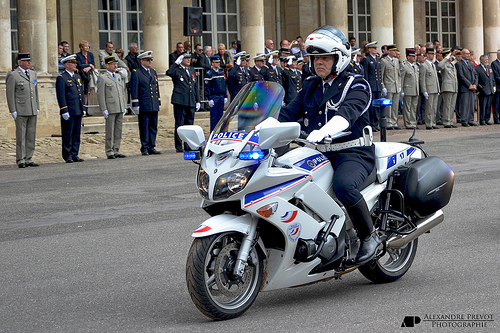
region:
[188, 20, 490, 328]
police on motorcycle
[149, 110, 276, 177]
blue lights flashing on motorcycle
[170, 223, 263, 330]
front tire of motorcycle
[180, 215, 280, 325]
front cover of tire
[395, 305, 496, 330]
watermark of photographer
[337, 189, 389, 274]
black motorcycle boots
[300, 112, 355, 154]
white gloves of officer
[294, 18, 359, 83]
officer's helmet on head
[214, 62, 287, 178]
shield on motorcycle for protection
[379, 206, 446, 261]
chrome exhaust pipe on bike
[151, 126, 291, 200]
flashing led lights on police motorcycle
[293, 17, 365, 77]
man wearing helmet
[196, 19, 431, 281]
police officer on motorcycle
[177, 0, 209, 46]
speaker for crowd to hear whats being said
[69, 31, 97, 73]
Woman in red shirt with blue jacket watching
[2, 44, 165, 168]
men of forces wearing the dress uniforms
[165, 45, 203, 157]
man standing saluting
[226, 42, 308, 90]
3 men saluting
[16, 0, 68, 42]
column of building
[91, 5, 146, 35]
windows of building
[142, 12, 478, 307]
policeman on motorcycle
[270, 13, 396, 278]
police in dress blues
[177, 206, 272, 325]
front tire of bike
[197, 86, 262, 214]
front shield of bike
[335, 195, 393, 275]
black riding boots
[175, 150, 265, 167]
blue lights flashing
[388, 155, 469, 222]
black box on back of bike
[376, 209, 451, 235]
chrome pipe on back of bike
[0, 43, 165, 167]
fellow officers line up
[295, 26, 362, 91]
white helmet on policeman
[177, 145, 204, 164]
blue lights on a motorcycle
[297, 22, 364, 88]
a helmet worn by a motorcyclist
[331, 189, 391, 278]
boots worn by a motorcyclist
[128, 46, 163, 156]
a man in a military uniform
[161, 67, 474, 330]
a police motorcycle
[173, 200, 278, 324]
a motorcycle wheel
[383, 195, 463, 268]
the exhaust pipe of a motorcycle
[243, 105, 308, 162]
rear view mirror on a motorcycle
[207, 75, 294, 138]
windscreen on a motorcycle.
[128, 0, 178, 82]
a column on a building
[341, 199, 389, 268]
Black boot worn by police officer on motorcycle.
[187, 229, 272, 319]
Front wheel of the motorcycle.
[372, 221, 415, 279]
Back wheel of the motorcycle.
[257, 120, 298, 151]
Right side view mirror on the motorcycle.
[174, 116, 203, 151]
Left side view mirror of the motorcycle.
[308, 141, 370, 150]
White belt worn by the police officer on the motorcycle.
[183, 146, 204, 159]
Left blue light on the front of the motorcycle.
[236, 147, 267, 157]
Right blue light on the front of the motorcycle.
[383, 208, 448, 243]
Chrome tail pipe/muffler of the motorcycle.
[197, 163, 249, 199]
Two front headlights on the motorcycle.